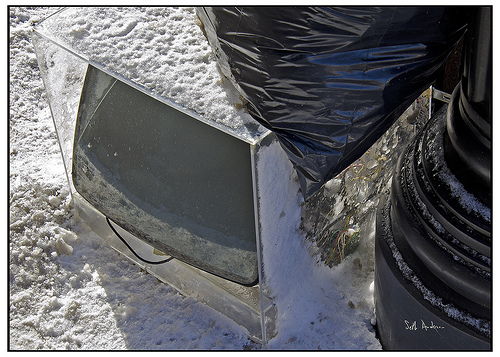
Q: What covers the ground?
A: Snow.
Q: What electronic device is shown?
A: TV.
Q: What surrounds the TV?
A: A plastic case.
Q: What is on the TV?
A: Snow.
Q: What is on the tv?
A: A garbage bag.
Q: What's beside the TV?
A: A black pole.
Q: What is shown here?
A: Garbage.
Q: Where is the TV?
A: On the ground.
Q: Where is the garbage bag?
A: On the TV.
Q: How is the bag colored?
A: Black.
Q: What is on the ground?
A: Snow.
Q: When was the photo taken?
A: Winter season.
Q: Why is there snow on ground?
A: Winter season.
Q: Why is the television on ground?
A: Discarded.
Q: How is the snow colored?
A: In white.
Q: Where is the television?
A: On snowy ground.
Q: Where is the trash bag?
A: On television.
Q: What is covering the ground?
A: Snow.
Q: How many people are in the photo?
A: None.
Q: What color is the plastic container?
A: Clear.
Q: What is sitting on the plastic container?
A: Trash bag.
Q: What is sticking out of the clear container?
A: Wire.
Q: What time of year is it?
A: Winter.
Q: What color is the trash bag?
A: Black.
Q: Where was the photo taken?
A: On a beach.